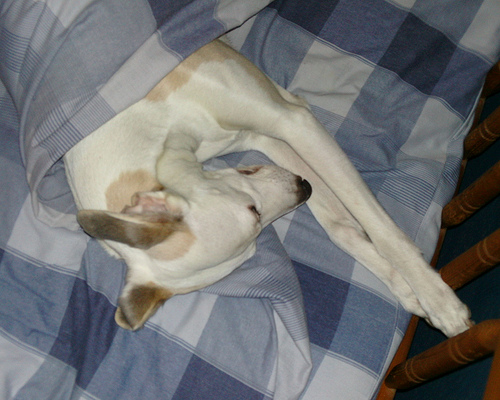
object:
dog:
[63, 38, 475, 340]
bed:
[3, 1, 499, 399]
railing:
[385, 64, 500, 400]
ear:
[76, 191, 185, 249]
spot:
[105, 171, 163, 215]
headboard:
[371, 59, 500, 399]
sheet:
[2, 0, 312, 400]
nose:
[300, 179, 312, 201]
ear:
[113, 277, 172, 331]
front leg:
[217, 63, 439, 299]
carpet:
[393, 94, 497, 399]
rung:
[441, 163, 499, 230]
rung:
[438, 229, 499, 292]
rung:
[384, 317, 500, 391]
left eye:
[249, 206, 260, 221]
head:
[76, 164, 311, 331]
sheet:
[0, 0, 499, 400]